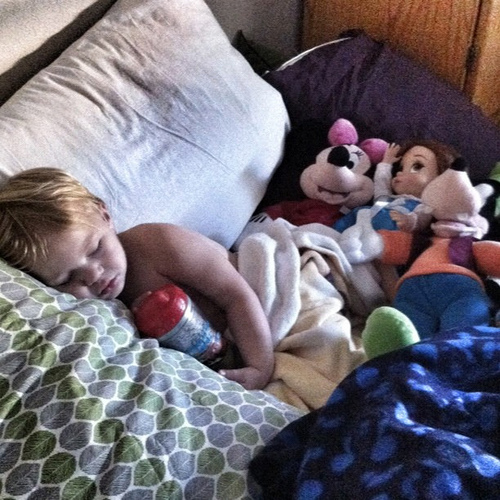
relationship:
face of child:
[56, 231, 124, 299] [0, 166, 275, 392]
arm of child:
[162, 240, 285, 387] [0, 166, 275, 392]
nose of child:
[81, 266, 106, 286] [0, 166, 275, 392]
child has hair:
[0, 166, 275, 392] [3, 169, 92, 248]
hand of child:
[220, 361, 266, 393] [0, 166, 275, 392]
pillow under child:
[4, 1, 296, 219] [0, 166, 275, 392]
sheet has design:
[4, 260, 313, 498] [2, 258, 312, 498]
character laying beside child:
[233, 118, 387, 251] [0, 166, 275, 392]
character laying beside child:
[330, 141, 462, 305] [0, 166, 275, 392]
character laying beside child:
[361, 158, 500, 361] [0, 166, 275, 392]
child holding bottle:
[0, 166, 275, 392] [134, 283, 225, 363]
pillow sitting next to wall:
[282, 23, 478, 134] [285, 1, 499, 108]